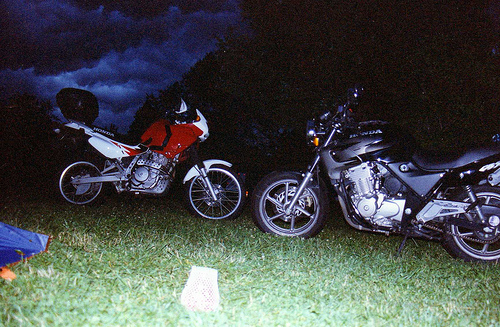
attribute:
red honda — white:
[55, 88, 243, 222]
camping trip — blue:
[1, 222, 52, 269]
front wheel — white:
[183, 159, 244, 224]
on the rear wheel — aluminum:
[57, 156, 105, 209]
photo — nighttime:
[2, 2, 499, 321]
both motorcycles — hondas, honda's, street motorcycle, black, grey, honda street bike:
[250, 71, 499, 261]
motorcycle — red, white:
[43, 85, 250, 228]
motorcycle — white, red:
[39, 77, 249, 221]